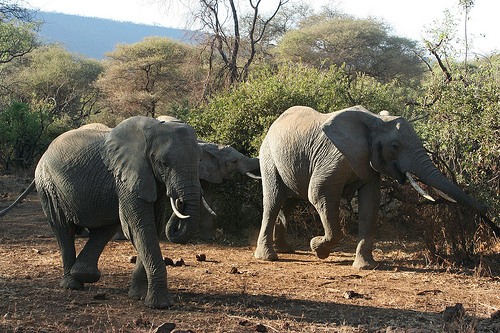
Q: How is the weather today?
A: It is clear.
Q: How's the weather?
A: It is clear.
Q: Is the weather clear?
A: Yes, it is clear.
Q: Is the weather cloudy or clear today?
A: It is clear.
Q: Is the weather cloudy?
A: No, it is clear.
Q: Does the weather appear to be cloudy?
A: No, it is clear.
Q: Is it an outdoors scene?
A: Yes, it is outdoors.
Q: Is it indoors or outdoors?
A: It is outdoors.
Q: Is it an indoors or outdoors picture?
A: It is outdoors.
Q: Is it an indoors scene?
A: No, it is outdoors.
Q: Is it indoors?
A: No, it is outdoors.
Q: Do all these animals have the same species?
A: Yes, all the animals are elephants.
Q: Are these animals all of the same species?
A: Yes, all the animals are elephants.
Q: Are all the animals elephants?
A: Yes, all the animals are elephants.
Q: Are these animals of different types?
A: No, all the animals are elephants.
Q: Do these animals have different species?
A: No, all the animals are elephants.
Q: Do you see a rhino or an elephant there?
A: Yes, there is an elephant.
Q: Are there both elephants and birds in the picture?
A: No, there is an elephant but no birds.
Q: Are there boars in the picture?
A: No, there are no boars.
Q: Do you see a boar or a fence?
A: No, there are no boars or fences.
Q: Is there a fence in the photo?
A: No, there are no fences.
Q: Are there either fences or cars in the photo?
A: No, there are no fences or cars.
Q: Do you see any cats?
A: No, there are no cats.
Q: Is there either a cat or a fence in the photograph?
A: No, there are no cats or fences.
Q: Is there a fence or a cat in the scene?
A: No, there are no cats or fences.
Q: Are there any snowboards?
A: No, there are no snowboards.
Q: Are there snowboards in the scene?
A: No, there are no snowboards.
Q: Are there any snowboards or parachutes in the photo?
A: No, there are no snowboards or parachutes.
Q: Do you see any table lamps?
A: No, there are no table lamps.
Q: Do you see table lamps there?
A: No, there are no table lamps.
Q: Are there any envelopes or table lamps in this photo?
A: No, there are no table lamps or envelopes.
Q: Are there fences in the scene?
A: No, there are no fences.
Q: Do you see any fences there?
A: No, there are no fences.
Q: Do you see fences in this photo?
A: No, there are no fences.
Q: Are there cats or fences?
A: No, there are no fences or cats.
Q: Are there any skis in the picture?
A: No, there are no skis.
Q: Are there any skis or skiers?
A: No, there are no skis or skiers.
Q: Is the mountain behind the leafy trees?
A: Yes, the mountain is behind the trees.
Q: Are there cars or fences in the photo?
A: No, there are no fences or cars.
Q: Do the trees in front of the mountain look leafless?
A: No, the trees are leafy.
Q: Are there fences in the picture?
A: No, there are no fences.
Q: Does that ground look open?
A: Yes, the ground is open.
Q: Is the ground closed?
A: No, the ground is open.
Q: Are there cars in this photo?
A: No, there are no cars.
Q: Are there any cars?
A: No, there are no cars.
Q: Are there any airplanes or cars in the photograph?
A: No, there are no cars or airplanes.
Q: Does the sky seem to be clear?
A: Yes, the sky is clear.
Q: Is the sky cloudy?
A: No, the sky is clear.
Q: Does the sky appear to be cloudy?
A: No, the sky is clear.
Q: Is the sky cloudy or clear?
A: The sky is clear.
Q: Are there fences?
A: No, there are no fences.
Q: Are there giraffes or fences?
A: No, there are no fences or giraffes.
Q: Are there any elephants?
A: Yes, there is an elephant.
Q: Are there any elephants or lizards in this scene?
A: Yes, there is an elephant.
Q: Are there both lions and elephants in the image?
A: No, there is an elephant but no lions.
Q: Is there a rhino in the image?
A: No, there are no rhinos.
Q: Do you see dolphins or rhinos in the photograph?
A: No, there are no rhinos or dolphins.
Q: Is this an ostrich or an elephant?
A: This is an elephant.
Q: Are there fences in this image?
A: No, there are no fences.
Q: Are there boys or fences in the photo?
A: No, there are no fences or boys.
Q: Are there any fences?
A: No, there are no fences.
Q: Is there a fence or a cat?
A: No, there are no fences or cats.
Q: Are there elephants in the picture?
A: Yes, there is an elephant.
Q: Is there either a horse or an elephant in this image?
A: Yes, there is an elephant.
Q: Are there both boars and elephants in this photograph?
A: No, there is an elephant but no boars.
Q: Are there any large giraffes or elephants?
A: Yes, there is a large elephant.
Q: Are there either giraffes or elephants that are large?
A: Yes, the elephant is large.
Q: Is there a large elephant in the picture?
A: Yes, there is a large elephant.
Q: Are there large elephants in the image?
A: Yes, there is a large elephant.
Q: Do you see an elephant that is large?
A: Yes, there is an elephant that is large.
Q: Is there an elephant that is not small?
A: Yes, there is a large elephant.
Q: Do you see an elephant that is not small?
A: Yes, there is a large elephant.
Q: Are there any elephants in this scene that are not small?
A: Yes, there is a large elephant.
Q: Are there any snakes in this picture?
A: No, there are no snakes.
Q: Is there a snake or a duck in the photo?
A: No, there are no snakes or ducks.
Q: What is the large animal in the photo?
A: The animal is an elephant.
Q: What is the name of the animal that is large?
A: The animal is an elephant.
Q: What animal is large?
A: The animal is an elephant.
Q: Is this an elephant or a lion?
A: This is an elephant.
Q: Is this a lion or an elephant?
A: This is an elephant.